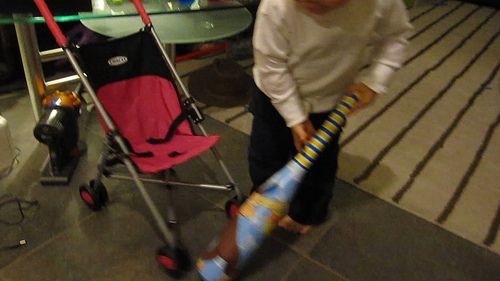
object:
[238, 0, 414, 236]
child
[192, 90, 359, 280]
bat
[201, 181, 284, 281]
charactors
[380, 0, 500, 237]
rug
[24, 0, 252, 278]
stroller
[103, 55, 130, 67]
logo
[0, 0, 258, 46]
table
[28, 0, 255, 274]
chair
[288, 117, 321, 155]
hands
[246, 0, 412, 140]
shirt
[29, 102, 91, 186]
fan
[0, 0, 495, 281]
floor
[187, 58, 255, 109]
hat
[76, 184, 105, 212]
wheels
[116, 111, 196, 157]
strap